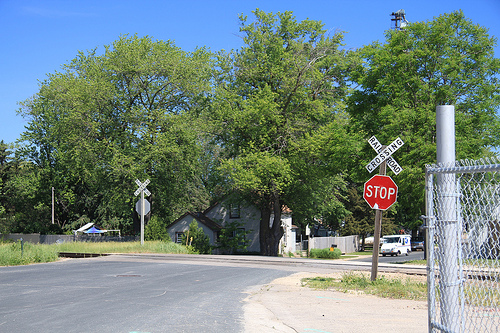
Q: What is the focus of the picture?
A: Railroad tracks.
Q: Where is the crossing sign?
A: Above the stop sign.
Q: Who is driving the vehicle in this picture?
A: Mailman.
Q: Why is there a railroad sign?
A: Trains cross there.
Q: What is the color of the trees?
A: Green.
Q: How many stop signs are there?
A: Two.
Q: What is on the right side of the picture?
A: A fence.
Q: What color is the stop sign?
A: Red.